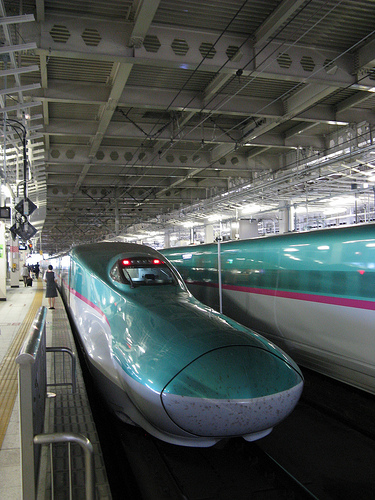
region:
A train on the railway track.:
[81, 240, 298, 444]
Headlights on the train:
[121, 258, 174, 266]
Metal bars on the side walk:
[41, 344, 80, 400]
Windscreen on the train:
[112, 265, 176, 285]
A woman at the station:
[39, 264, 60, 311]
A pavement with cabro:
[0, 298, 23, 317]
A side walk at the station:
[49, 306, 64, 336]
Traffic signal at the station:
[9, 236, 42, 254]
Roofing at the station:
[86, 99, 206, 181]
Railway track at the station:
[181, 456, 289, 495]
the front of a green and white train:
[139, 328, 303, 451]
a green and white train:
[46, 222, 307, 444]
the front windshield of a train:
[124, 264, 176, 285]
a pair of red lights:
[121, 258, 164, 263]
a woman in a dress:
[43, 263, 58, 310]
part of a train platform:
[0, 268, 58, 316]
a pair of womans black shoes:
[48, 304, 54, 309]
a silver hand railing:
[16, 304, 47, 497]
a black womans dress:
[43, 271, 58, 296]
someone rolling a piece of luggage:
[19, 263, 32, 289]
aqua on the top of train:
[161, 323, 224, 384]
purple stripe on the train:
[298, 286, 373, 316]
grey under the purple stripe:
[309, 309, 374, 329]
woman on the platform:
[45, 272, 60, 321]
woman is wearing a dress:
[49, 282, 66, 301]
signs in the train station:
[15, 200, 36, 241]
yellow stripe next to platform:
[21, 298, 41, 315]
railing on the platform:
[39, 338, 92, 386]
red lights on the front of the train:
[116, 242, 169, 267]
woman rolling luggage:
[27, 274, 39, 290]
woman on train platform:
[31, 261, 71, 318]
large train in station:
[38, 238, 308, 457]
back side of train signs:
[1, 111, 50, 255]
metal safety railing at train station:
[11, 292, 90, 499]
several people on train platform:
[14, 251, 46, 302]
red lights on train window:
[98, 242, 205, 330]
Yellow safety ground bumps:
[2, 298, 45, 415]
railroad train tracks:
[139, 441, 308, 498]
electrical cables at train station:
[90, 87, 314, 194]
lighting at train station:
[233, 190, 350, 229]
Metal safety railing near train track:
[21, 305, 100, 497]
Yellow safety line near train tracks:
[12, 296, 38, 369]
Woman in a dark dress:
[38, 263, 66, 313]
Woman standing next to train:
[41, 262, 63, 312]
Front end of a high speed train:
[117, 305, 315, 458]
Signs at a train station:
[8, 210, 39, 249]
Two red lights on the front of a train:
[117, 255, 172, 270]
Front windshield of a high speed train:
[100, 247, 192, 299]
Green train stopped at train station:
[63, 237, 310, 463]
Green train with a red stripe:
[203, 232, 319, 305]